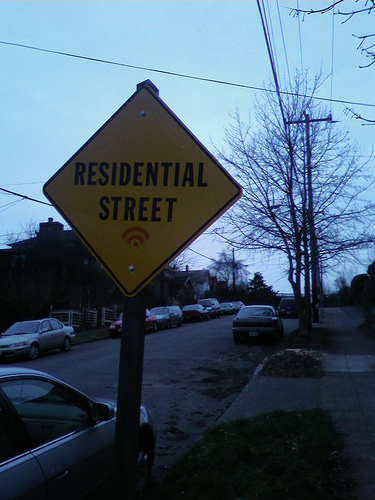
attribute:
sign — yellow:
[41, 84, 243, 295]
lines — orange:
[119, 228, 148, 249]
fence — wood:
[51, 308, 116, 326]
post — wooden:
[284, 110, 332, 324]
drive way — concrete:
[210, 373, 373, 423]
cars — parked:
[1, 301, 244, 361]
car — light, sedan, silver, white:
[0, 319, 77, 360]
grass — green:
[153, 409, 359, 491]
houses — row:
[0, 219, 228, 312]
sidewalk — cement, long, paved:
[322, 305, 374, 499]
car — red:
[109, 310, 155, 338]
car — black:
[230, 306, 283, 344]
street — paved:
[1, 314, 299, 478]